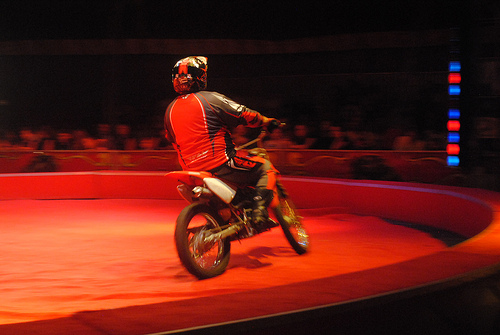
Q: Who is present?
A: A biker.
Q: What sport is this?
A: Biking.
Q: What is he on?
A: A bike.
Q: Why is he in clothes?
A: To keep warm.